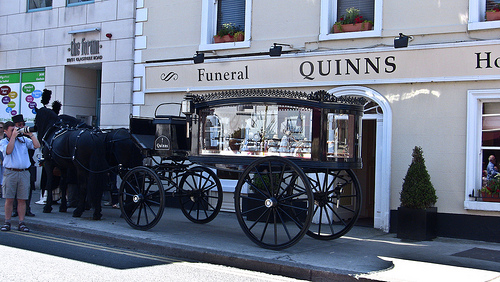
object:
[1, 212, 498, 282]
road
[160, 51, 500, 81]
words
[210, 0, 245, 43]
window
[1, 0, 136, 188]
building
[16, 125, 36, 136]
camera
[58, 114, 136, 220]
horses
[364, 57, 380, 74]
letter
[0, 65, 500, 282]
ground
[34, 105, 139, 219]
black horse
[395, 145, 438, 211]
tree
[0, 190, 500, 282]
side walk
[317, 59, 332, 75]
letter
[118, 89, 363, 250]
carriage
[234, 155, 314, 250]
wheel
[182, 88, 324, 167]
wall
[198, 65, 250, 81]
letter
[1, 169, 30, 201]
shorts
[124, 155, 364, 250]
wheels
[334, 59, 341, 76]
letter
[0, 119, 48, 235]
man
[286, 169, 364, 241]
wheel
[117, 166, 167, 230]
wheel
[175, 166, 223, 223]
wheel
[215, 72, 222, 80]
black letter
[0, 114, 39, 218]
man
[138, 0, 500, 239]
building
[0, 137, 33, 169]
shirt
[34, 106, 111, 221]
horse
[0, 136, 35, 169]
dress shirt